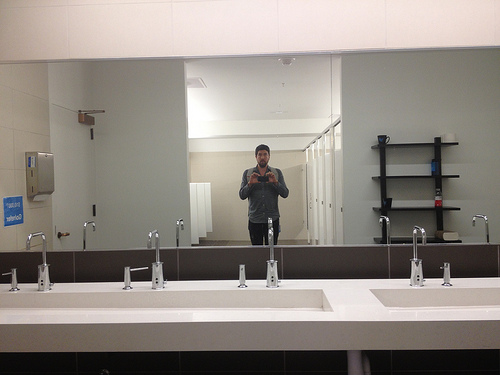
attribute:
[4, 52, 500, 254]
mirror — here, reflecting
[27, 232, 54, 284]
faucet — here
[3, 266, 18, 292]
soap — here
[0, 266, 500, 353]
sink — long, pink, white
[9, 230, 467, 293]
pipes — here, running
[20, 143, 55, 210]
napkins — here, paper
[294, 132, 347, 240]
stalls — here, white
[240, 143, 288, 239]
man — here, wearing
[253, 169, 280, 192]
camera — here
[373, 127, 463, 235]
shelf — here, empty, black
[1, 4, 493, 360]
bathroom — public, here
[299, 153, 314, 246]
door — here